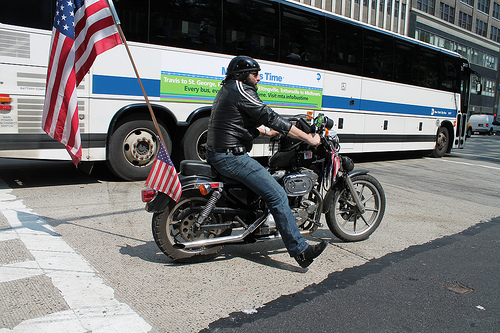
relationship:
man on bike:
[203, 41, 337, 272] [135, 114, 381, 262]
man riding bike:
[203, 41, 337, 272] [135, 114, 381, 262]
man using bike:
[203, 41, 337, 272] [135, 114, 381, 262]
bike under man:
[135, 114, 381, 262] [203, 41, 337, 272]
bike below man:
[135, 114, 381, 262] [203, 41, 337, 272]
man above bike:
[203, 41, 337, 272] [135, 114, 381, 262]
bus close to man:
[0, 2, 477, 163] [203, 41, 337, 272]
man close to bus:
[203, 41, 337, 272] [0, 2, 477, 163]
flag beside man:
[39, 1, 179, 203] [203, 41, 337, 272]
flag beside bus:
[39, 1, 179, 203] [0, 2, 477, 163]